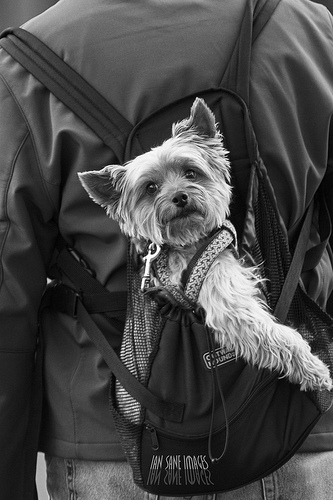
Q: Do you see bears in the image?
A: No, there are no bears.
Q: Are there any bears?
A: No, there are no bears.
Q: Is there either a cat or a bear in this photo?
A: No, there are no bears or cats.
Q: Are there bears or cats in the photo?
A: No, there are no bears or cats.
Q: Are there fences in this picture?
A: No, there are no fences.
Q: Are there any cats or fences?
A: No, there are no fences or cats.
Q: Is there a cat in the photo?
A: No, there are no cats.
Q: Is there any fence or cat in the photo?
A: No, there are no cats or fences.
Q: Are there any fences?
A: No, there are no fences.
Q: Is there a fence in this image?
A: No, there are no fences.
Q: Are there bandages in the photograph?
A: No, there are no bandages.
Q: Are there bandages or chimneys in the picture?
A: No, there are no bandages or chimneys.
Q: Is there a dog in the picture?
A: Yes, there is a dog.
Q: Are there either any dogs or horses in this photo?
A: Yes, there is a dog.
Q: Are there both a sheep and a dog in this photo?
A: No, there is a dog but no sheep.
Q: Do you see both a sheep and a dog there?
A: No, there is a dog but no sheep.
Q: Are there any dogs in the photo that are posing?
A: Yes, there is a dog that is posing.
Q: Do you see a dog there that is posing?
A: Yes, there is a dog that is posing.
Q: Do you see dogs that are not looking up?
A: Yes, there is a dog that is posing .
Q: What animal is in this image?
A: The animal is a dog.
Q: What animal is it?
A: The animal is a dog.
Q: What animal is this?
A: This is a dog.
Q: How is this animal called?
A: This is a dog.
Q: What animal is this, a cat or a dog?
A: This is a dog.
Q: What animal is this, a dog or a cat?
A: This is a dog.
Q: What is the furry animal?
A: The animal is a dog.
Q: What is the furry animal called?
A: The animal is a dog.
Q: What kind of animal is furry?
A: The animal is a dog.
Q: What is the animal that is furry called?
A: The animal is a dog.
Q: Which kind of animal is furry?
A: The animal is a dog.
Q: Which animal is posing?
A: The animal is a dog.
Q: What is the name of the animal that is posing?
A: The animal is a dog.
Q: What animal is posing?
A: The animal is a dog.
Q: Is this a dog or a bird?
A: This is a dog.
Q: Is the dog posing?
A: Yes, the dog is posing.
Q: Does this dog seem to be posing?
A: Yes, the dog is posing.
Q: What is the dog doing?
A: The dog is posing.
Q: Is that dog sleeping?
A: No, the dog is posing.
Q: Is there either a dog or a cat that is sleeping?
A: No, there is a dog but it is posing.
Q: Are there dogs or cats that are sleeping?
A: No, there is a dog but it is posing.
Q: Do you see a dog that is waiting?
A: No, there is a dog but it is posing.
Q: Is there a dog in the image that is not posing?
A: No, there is a dog but it is posing.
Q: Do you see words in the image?
A: Yes, there are words.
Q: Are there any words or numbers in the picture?
A: Yes, there are words.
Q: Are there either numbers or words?
A: Yes, there are words.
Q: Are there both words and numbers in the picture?
A: No, there are words but no numbers.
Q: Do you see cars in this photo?
A: No, there are no cars.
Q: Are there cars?
A: No, there are no cars.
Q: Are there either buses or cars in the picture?
A: No, there are no cars or buses.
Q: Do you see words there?
A: Yes, there are words.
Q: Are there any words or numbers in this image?
A: Yes, there are words.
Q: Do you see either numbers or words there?
A: Yes, there are words.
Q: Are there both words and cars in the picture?
A: No, there are words but no cars.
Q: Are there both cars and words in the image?
A: No, there are words but no cars.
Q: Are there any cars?
A: No, there are no cars.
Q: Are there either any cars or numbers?
A: No, there are no cars or numbers.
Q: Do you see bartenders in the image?
A: No, there are no bartenders.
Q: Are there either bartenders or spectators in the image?
A: No, there are no bartenders or spectators.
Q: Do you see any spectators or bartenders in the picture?
A: No, there are no bartenders or spectators.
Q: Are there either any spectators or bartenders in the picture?
A: No, there are no bartenders or spectators.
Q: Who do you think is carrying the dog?
A: The man is carrying the dog.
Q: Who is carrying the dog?
A: The man is carrying the dog.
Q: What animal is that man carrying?
A: The man is carrying a dog.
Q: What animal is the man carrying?
A: The man is carrying a dog.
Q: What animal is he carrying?
A: The man is carrying a dog.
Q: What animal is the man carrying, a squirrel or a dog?
A: The man is carrying a dog.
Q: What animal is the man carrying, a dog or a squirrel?
A: The man is carrying a dog.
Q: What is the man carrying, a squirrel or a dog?
A: The man is carrying a dog.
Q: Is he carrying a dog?
A: Yes, the man is carrying a dog.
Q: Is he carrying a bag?
A: No, the man is carrying a dog.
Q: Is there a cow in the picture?
A: No, there are no cows.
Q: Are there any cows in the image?
A: No, there are no cows.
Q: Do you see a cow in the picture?
A: No, there are no cows.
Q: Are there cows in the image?
A: No, there are no cows.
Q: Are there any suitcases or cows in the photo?
A: No, there are no cows or suitcases.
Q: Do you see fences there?
A: No, there are no fences.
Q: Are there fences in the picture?
A: No, there are no fences.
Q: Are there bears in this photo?
A: No, there are no bears.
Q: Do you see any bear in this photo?
A: No, there are no bears.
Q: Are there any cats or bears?
A: No, there are no bears or cats.